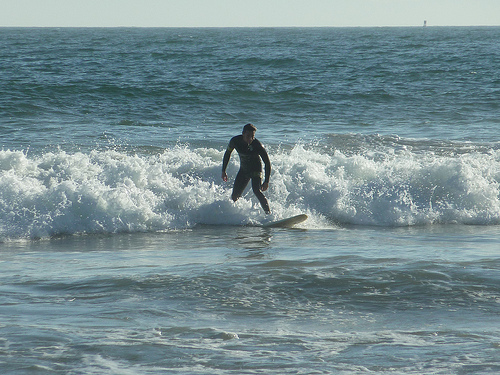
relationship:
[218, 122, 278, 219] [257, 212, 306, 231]
man on surfboard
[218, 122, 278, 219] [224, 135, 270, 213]
man wearing wetsuit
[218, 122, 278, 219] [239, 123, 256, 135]
man has hair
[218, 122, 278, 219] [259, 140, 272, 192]
man has arm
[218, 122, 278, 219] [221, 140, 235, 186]
man has arm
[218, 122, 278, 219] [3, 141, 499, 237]
man on wave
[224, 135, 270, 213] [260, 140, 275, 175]
wetsuit has sleeve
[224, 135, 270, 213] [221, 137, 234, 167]
wetsuit has sleeve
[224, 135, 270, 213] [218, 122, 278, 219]
wetsuit on man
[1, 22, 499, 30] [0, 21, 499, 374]
horizon over water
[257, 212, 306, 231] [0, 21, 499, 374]
surfboard in water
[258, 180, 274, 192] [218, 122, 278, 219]
hand of man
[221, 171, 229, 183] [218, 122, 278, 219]
hand of man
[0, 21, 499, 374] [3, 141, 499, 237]
water has wave